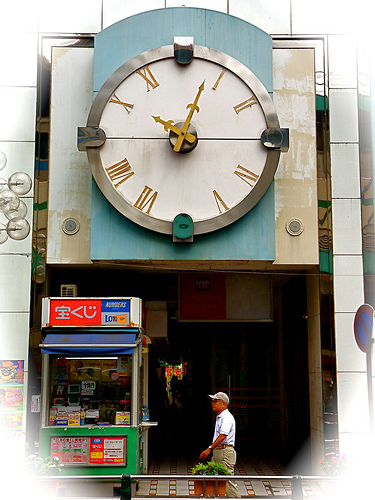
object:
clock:
[77, 36, 292, 245]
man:
[200, 390, 240, 475]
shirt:
[211, 406, 238, 446]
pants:
[210, 447, 241, 497]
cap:
[207, 391, 230, 405]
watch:
[206, 444, 214, 452]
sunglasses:
[211, 397, 225, 406]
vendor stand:
[34, 294, 161, 473]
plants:
[192, 462, 230, 497]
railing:
[28, 471, 370, 494]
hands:
[148, 77, 212, 154]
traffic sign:
[347, 304, 373, 353]